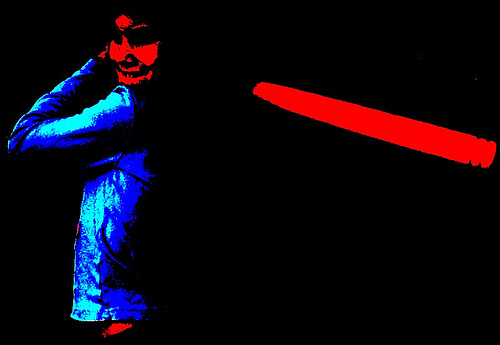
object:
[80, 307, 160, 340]
waist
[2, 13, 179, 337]
woman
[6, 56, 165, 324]
shirt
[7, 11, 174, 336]
body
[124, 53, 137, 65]
nose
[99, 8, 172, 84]
face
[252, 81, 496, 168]
sword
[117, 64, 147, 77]
mouth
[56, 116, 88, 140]
elbow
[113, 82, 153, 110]
shoulder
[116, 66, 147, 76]
lip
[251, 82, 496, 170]
bat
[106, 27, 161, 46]
eyes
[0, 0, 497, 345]
area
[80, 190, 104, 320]
lights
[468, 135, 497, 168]
end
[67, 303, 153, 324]
belt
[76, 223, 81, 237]
button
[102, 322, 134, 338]
part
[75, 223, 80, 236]
bit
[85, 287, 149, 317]
stomach